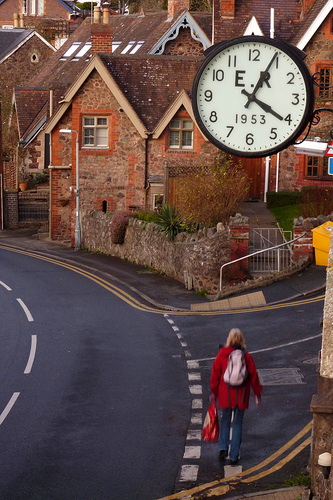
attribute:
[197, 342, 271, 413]
coat — red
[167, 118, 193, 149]
window — small 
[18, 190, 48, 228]
brick steps — brick 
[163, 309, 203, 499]
dotted line — dotted 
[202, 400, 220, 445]
tote bag — red, plastic 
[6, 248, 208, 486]
road — white , yellow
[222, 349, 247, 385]
backpack — pink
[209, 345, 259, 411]
jacket — red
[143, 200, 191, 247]
tree — small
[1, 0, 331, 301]
houses — brick 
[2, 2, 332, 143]
roofs — angled, slanted, tiled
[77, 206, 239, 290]
fence — stone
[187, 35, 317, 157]
clock — black, white, round , public 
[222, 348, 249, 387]
backpack — light colored, white , black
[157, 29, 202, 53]
border — gray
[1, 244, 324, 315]
line — long 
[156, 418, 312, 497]
line — long 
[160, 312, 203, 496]
line — long 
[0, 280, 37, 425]
line — long 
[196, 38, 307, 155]
round clock — round 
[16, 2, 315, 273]
houses — stone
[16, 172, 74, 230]
stairs — brick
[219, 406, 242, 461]
jeans — blue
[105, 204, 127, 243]
vines — brown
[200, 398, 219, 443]
bag — red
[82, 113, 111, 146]
window — small 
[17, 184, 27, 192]
flowerpot — clay 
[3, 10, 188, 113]
roof — slanted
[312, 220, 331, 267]
trash receptacle — yellow 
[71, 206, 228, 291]
wall — stone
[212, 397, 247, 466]
jeans — blue 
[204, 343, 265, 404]
jacket — red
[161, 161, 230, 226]
partition — wooden